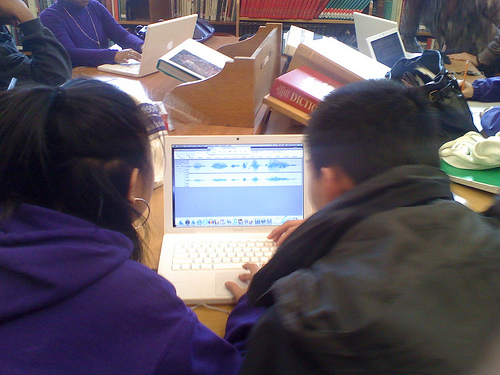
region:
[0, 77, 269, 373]
woman wearing purple sweatshirt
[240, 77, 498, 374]
man wearing grey coat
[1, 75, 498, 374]
woman and man on laptop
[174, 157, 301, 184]
audio files on laptop screen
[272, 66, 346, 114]
red dictionary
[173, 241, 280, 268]
white keyboard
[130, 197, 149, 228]
silver hoop earring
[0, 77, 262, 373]
woman with ponytail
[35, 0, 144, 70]
woman wearing purple sweater in background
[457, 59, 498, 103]
person holding orange pencil in background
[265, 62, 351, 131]
a big red dictionary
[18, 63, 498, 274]
two people sharing a computer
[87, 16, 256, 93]
a laptop with an apple logo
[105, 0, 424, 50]
a shelf full of books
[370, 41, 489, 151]
a black purse on the table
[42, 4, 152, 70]
a purple sweater and gold necklace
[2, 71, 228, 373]
a girl with a ponytail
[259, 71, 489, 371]
a male in a brown coat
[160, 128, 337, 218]
sound waves on a computer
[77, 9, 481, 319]
four laptops on the table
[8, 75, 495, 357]
girl and boy watching screen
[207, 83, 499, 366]
boy typing on computer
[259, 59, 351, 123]
red dictionary on desk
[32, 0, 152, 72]
woman wearing purple shirt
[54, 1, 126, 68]
woman wearing gold necklace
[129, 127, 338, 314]
typing on white laptop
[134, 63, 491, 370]
boy editing audio files on laptop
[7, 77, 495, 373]
girl and boy with black hair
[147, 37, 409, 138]
books on wooden desk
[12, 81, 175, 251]
girl with gold hoop earrings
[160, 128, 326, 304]
a small white laptop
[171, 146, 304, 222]
a blue and white screen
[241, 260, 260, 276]
a long finger on keyboard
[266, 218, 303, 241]
a long finger on keyboard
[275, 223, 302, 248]
a long finger on keyboard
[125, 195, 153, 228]
a large silver hoop earring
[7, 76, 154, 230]
an ear on a the head of a woman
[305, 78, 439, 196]
a head with black hair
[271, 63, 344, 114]
a red and white dictionary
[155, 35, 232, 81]
a blue and white book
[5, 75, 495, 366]
two people looking at a laptop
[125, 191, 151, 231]
the girl has hoop earrings on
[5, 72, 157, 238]
the girl has black hair in a ponytail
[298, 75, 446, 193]
the boy has short black hair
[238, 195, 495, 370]
the boy is wearing a black jacket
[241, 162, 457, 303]
a scarf is around the neck of the boy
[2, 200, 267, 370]
the girl has a purple fleece jacket on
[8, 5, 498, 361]
students are studying on tables and desks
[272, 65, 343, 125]
a red dictionary is on the table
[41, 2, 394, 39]
shelves of books are behind the students